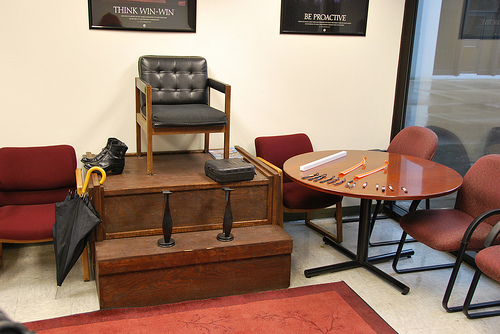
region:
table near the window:
[293, 140, 453, 282]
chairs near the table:
[260, 131, 499, 297]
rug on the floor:
[15, 286, 411, 331]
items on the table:
[301, 139, 416, 199]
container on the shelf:
[203, 152, 256, 180]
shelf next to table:
[67, 140, 293, 232]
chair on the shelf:
[127, 44, 240, 164]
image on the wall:
[263, 0, 377, 47]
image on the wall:
[76, 3, 204, 42]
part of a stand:
[358, 205, 392, 250]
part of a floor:
[296, 226, 331, 281]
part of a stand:
[366, 205, 398, 231]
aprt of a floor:
[316, 245, 348, 291]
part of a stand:
[358, 241, 397, 288]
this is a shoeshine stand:
[78, 46, 300, 309]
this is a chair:
[112, 30, 237, 176]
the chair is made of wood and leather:
[124, 50, 245, 180]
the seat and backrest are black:
[130, 32, 237, 145]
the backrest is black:
[122, 52, 227, 107]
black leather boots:
[77, 134, 149, 184]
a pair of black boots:
[64, 125, 148, 177]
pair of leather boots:
[72, 128, 148, 188]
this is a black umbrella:
[31, 142, 119, 300]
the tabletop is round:
[269, 99, 471, 295]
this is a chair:
[133, 50, 225, 152]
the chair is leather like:
[164, 63, 206, 102]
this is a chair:
[412, 159, 438, 188]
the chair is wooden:
[397, 157, 440, 181]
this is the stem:
[345, 205, 378, 260]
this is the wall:
[292, 37, 379, 107]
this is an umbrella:
[40, 172, 99, 267]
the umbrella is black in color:
[40, 200, 97, 287]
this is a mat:
[284, 287, 340, 332]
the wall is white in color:
[294, 45, 349, 100]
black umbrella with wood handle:
[33, 154, 124, 283]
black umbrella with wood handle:
[37, 160, 121, 285]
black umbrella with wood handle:
[31, 145, 122, 288]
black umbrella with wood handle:
[32, 154, 112, 293]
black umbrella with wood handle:
[33, 146, 130, 287]